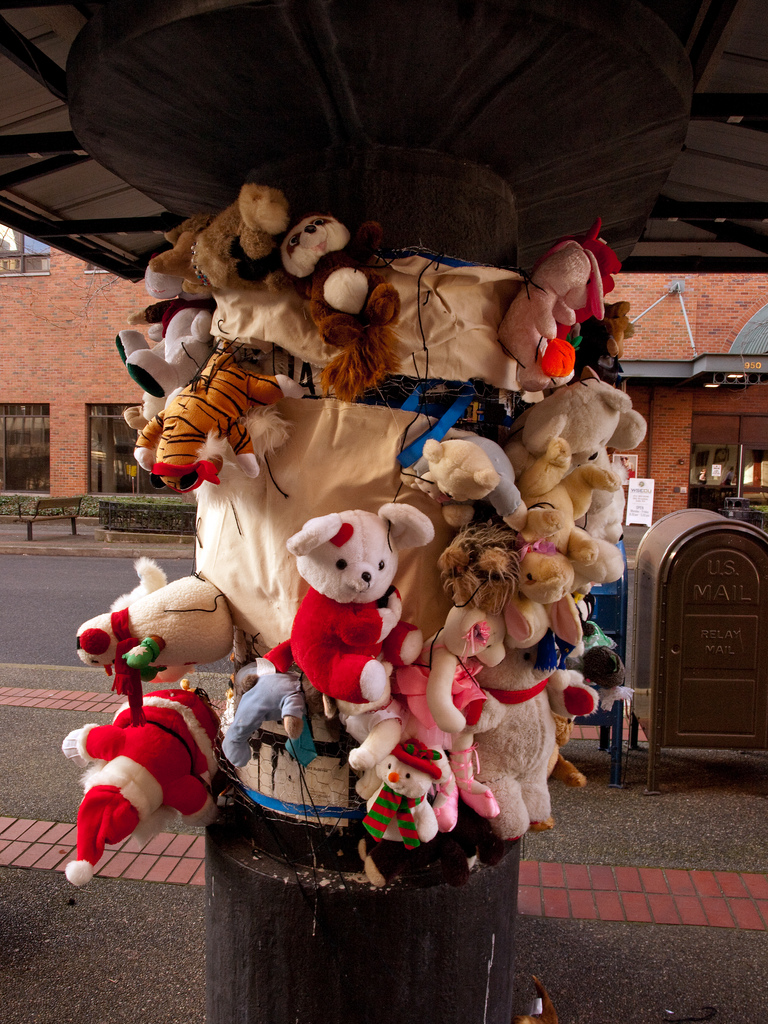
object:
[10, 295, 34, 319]
bricks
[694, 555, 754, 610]
words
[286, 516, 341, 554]
ear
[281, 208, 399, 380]
animals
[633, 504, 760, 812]
mailbox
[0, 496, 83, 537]
bench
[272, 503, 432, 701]
mouse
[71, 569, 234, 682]
penguin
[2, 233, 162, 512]
building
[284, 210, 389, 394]
bear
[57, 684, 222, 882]
stuffed santa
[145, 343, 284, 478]
tiger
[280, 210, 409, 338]
teddy bear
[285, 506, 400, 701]
teddy bear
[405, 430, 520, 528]
teddy bear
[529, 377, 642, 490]
teddy bear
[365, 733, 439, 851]
snowman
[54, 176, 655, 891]
group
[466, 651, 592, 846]
teddy bear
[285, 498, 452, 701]
teddy bear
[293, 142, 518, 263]
pole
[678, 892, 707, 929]
tile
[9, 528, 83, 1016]
ground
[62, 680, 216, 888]
stuffed animal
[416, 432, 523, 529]
stuffed animal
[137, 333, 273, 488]
stuffed animal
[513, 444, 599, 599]
stuffed animals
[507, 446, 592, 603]
teddy bear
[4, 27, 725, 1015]
object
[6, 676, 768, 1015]
sidewalk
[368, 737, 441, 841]
stuffed animal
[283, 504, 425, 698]
stuffed animal